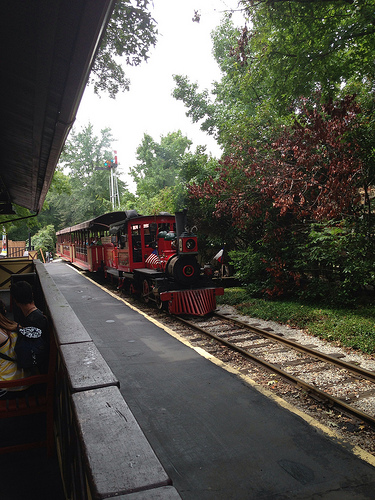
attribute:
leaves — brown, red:
[186, 92, 366, 231]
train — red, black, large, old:
[54, 209, 226, 317]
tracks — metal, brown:
[166, 307, 367, 423]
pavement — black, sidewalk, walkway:
[41, 259, 367, 493]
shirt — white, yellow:
[1, 330, 19, 381]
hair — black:
[10, 281, 34, 304]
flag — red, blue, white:
[144, 248, 158, 264]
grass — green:
[217, 283, 373, 354]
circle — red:
[182, 264, 196, 279]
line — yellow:
[63, 259, 370, 459]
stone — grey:
[72, 384, 170, 492]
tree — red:
[186, 87, 372, 295]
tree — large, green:
[171, 6, 370, 177]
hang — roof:
[5, 1, 111, 227]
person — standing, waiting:
[45, 246, 52, 262]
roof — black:
[110, 209, 174, 230]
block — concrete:
[59, 339, 120, 445]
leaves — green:
[219, 5, 366, 111]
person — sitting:
[1, 313, 29, 395]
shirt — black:
[21, 309, 53, 377]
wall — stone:
[29, 259, 177, 498]